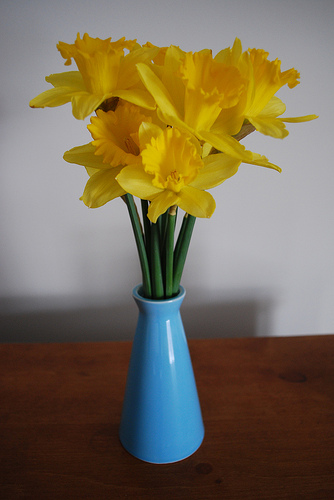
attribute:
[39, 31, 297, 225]
flowers — yellow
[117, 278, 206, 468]
vase — blue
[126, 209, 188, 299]
stems — green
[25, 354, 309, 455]
table — brown, wooden